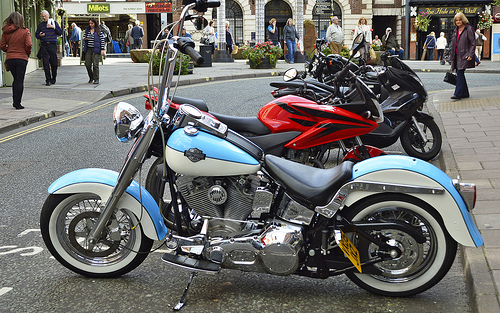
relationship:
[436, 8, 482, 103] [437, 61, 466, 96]
woman holding purse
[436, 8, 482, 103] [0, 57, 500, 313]
woman on ground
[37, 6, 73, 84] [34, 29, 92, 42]
pepole are holding phones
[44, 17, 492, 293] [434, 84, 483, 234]
motorbikes parked at sidewalk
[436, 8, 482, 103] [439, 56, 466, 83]
woman carrying bag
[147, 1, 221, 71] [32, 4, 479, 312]
handlebars on a motorcycle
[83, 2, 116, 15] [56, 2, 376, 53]
sign on building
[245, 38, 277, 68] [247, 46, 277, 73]
flowers in pot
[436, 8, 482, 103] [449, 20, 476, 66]
woman wearing jacket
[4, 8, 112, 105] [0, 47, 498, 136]
people walking on sidewalk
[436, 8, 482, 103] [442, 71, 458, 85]
woman carrying bag